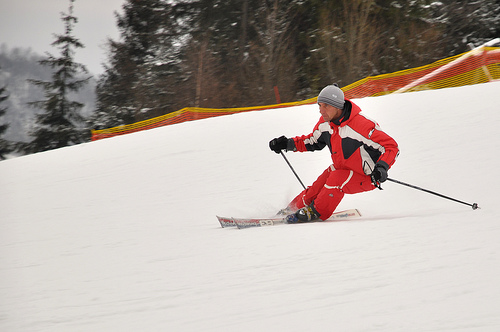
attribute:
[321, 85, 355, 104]
hat — grey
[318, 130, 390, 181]
jacket — red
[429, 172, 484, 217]
skis — black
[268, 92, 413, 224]
man — skiing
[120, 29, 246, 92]
trees — snowy, far, green, tall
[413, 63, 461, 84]
fence — orange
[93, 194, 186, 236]
snow — white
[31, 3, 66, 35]
sky — blue